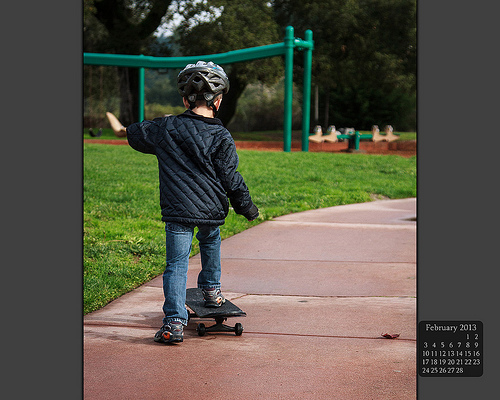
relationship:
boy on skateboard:
[107, 63, 276, 345] [183, 285, 246, 339]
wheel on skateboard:
[193, 324, 204, 340] [185, 286, 245, 337]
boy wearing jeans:
[107, 63, 276, 345] [162, 213, 227, 323]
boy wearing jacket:
[107, 63, 276, 345] [127, 116, 259, 224]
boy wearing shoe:
[107, 63, 276, 345] [152, 290, 229, 343]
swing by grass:
[87, 64, 104, 137] [86, 138, 410, 306]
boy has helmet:
[119, 57, 266, 345] [178, 58, 229, 107]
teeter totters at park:
[303, 108, 407, 161] [87, 7, 411, 387]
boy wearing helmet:
[107, 63, 276, 345] [174, 60, 231, 104]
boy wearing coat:
[119, 57, 266, 345] [120, 108, 256, 234]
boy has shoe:
[119, 57, 266, 345] [101, 260, 310, 380]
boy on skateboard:
[107, 63, 276, 345] [176, 282, 246, 337]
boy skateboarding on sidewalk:
[119, 57, 266, 345] [82, 194, 417, 399]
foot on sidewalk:
[149, 280, 193, 350] [90, 225, 417, 399]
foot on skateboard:
[193, 271, 231, 313] [167, 258, 257, 343]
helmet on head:
[174, 60, 231, 104] [189, 72, 216, 109]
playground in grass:
[86, 23, 410, 154] [86, 138, 410, 306]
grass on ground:
[262, 158, 315, 202] [82, 133, 404, 394]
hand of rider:
[94, 105, 135, 144] [124, 52, 275, 350]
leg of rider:
[196, 229, 246, 321] [102, 51, 265, 360]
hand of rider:
[213, 127, 263, 218] [102, 51, 265, 360]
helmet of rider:
[174, 60, 229, 107] [106, 58, 262, 341]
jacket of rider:
[127, 116, 259, 224] [106, 58, 262, 341]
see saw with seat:
[308, 119, 405, 150] [369, 123, 384, 145]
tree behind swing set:
[88, 0, 166, 127] [79, 22, 326, 156]